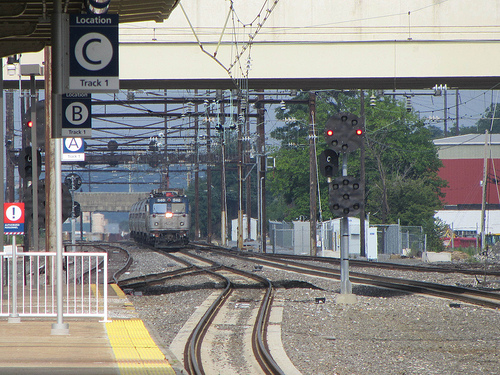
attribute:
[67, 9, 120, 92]
sign — black, white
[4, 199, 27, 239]
sign — blue, red, white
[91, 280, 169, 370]
edge — yellow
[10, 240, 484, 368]
rocks — grey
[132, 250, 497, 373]
gravel — gray 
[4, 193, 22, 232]
sign — red and blue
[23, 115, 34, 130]
light — red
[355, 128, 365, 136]
light — red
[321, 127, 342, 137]
light — red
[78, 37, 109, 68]
letter c — black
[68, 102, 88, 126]
circle — white